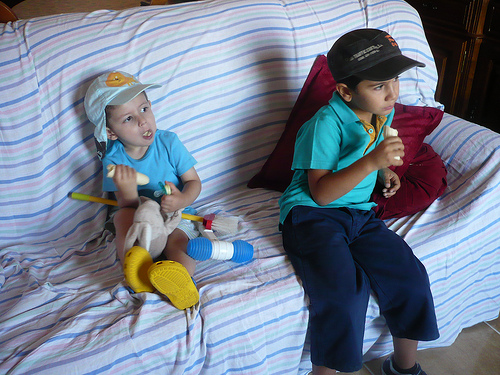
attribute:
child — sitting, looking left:
[82, 67, 202, 313]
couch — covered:
[3, 3, 499, 374]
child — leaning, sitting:
[277, 26, 440, 372]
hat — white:
[81, 68, 164, 163]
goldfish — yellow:
[107, 70, 138, 90]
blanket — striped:
[2, 6, 499, 375]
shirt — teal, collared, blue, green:
[274, 84, 397, 230]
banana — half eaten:
[382, 123, 403, 166]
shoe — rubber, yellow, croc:
[147, 261, 201, 310]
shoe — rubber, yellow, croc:
[123, 245, 159, 296]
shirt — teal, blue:
[100, 128, 200, 218]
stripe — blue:
[374, 19, 421, 30]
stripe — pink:
[366, 3, 414, 11]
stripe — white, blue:
[401, 42, 430, 52]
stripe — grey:
[463, 135, 499, 167]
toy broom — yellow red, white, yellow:
[70, 193, 240, 236]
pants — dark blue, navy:
[281, 199, 439, 373]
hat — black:
[324, 25, 426, 93]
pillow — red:
[243, 53, 443, 200]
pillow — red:
[369, 143, 450, 221]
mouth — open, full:
[139, 127, 154, 143]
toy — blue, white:
[185, 208, 256, 264]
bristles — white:
[212, 213, 240, 237]